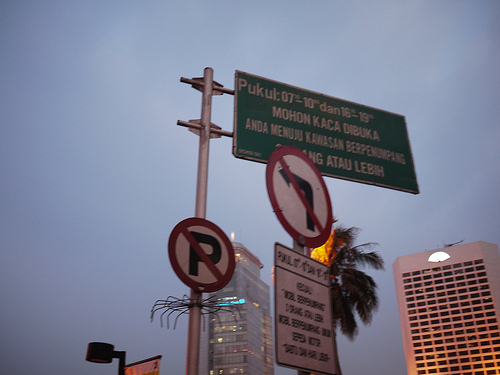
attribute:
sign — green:
[232, 74, 422, 194]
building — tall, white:
[389, 239, 498, 373]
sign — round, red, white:
[267, 144, 331, 242]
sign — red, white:
[169, 219, 235, 293]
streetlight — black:
[86, 339, 127, 374]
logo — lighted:
[425, 249, 451, 266]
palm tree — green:
[325, 221, 386, 337]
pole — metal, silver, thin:
[187, 58, 216, 375]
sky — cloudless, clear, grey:
[4, 2, 495, 374]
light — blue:
[219, 300, 252, 306]